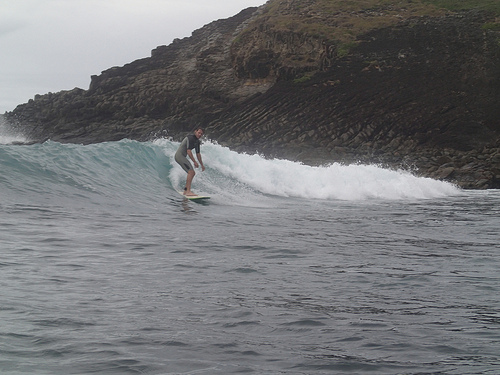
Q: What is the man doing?
A: Surfing.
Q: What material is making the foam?
A: Water.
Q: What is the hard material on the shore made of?
A: Rock.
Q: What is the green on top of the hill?
A: Grass.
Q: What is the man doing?
A: Surfing.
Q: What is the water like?
A: Choppy.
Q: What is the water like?
A: Buoyant.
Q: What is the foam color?
A: White.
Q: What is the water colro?
A: Gray.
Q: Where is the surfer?
A: Ocean.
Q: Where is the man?
A: On the surfboard.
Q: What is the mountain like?
A: Rocky.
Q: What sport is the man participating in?
A: Surfing.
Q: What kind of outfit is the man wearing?
A: Wet suit.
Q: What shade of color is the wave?
A: White.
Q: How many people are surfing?
A: One.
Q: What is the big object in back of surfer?
A: A rock.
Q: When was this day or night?
A: Day.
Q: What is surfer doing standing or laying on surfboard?
A: Standing .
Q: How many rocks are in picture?
A: One.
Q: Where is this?
A: On the ocean .